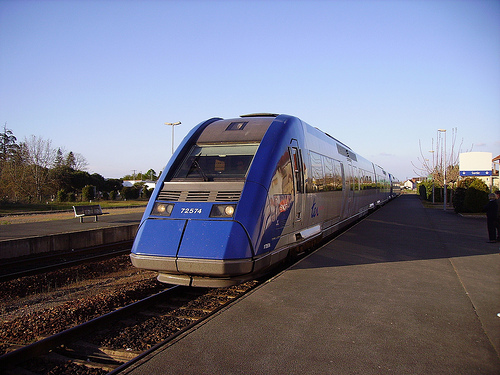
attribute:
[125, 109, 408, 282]
train — blue, long, silver, gray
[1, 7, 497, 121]
sky — blue, clear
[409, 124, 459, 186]
small tree — bare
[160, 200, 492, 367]
pavement — gray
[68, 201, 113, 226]
bench — empty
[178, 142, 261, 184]
windshield — rectangular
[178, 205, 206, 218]
numbers — white